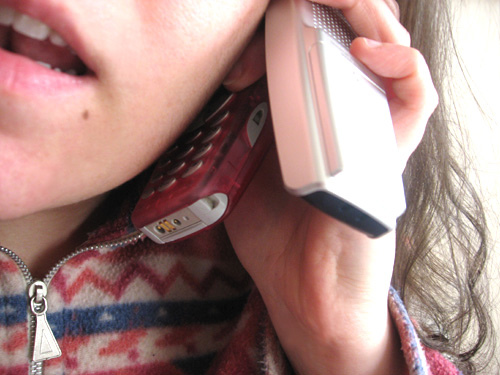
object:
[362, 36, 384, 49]
nail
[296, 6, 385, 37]
stuffed animal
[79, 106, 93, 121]
mole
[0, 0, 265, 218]
girls face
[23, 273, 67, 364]
zipper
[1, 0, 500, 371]
girl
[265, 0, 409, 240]
phone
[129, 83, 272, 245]
phone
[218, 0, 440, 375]
hand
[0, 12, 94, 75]
teeth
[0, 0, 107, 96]
mouth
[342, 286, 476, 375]
sleeve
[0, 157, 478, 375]
jacket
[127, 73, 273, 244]
case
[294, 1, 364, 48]
speaker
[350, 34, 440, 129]
finger